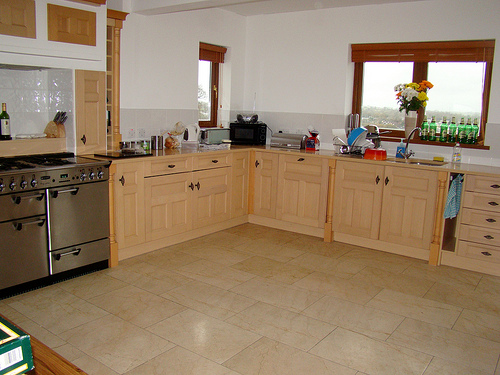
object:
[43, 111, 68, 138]
knives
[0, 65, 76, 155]
tiles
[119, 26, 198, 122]
wall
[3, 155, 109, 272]
stove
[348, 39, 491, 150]
window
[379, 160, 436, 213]
ground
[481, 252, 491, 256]
handle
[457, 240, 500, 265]
drawer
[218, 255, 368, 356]
phone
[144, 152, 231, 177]
drawers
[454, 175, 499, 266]
drawers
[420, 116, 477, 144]
bottles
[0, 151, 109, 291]
cooker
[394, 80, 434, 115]
flowers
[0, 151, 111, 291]
oven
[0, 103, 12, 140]
bottle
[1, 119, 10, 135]
label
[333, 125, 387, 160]
dishes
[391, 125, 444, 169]
sink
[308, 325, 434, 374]
tile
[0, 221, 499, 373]
floor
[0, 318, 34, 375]
box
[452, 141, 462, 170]
bottle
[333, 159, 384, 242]
door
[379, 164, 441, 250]
door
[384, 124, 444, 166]
sink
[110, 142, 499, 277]
wooden cupboards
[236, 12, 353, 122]
white wall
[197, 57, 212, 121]
window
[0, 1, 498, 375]
kitchen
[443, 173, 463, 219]
towel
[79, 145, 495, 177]
countertop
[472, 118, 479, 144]
bottle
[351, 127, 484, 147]
sill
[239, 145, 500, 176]
counter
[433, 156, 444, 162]
dish